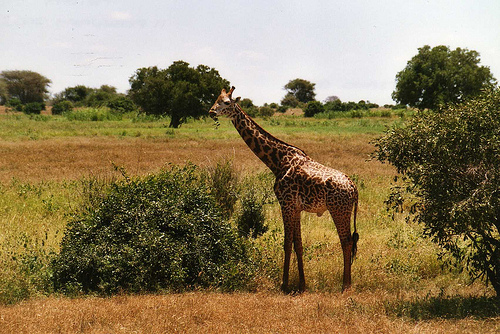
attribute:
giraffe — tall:
[208, 85, 358, 292]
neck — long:
[232, 105, 283, 175]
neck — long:
[223, 101, 303, 168]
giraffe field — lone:
[3, 41, 496, 331]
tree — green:
[131, 63, 223, 130]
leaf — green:
[149, 76, 166, 85]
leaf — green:
[181, 90, 196, 102]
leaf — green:
[173, 75, 190, 85]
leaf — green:
[145, 100, 160, 115]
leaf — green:
[176, 63, 184, 72]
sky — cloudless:
[0, 5, 498, 99]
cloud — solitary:
[105, 6, 142, 28]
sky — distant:
[2, 3, 499, 109]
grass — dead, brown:
[24, 262, 420, 327]